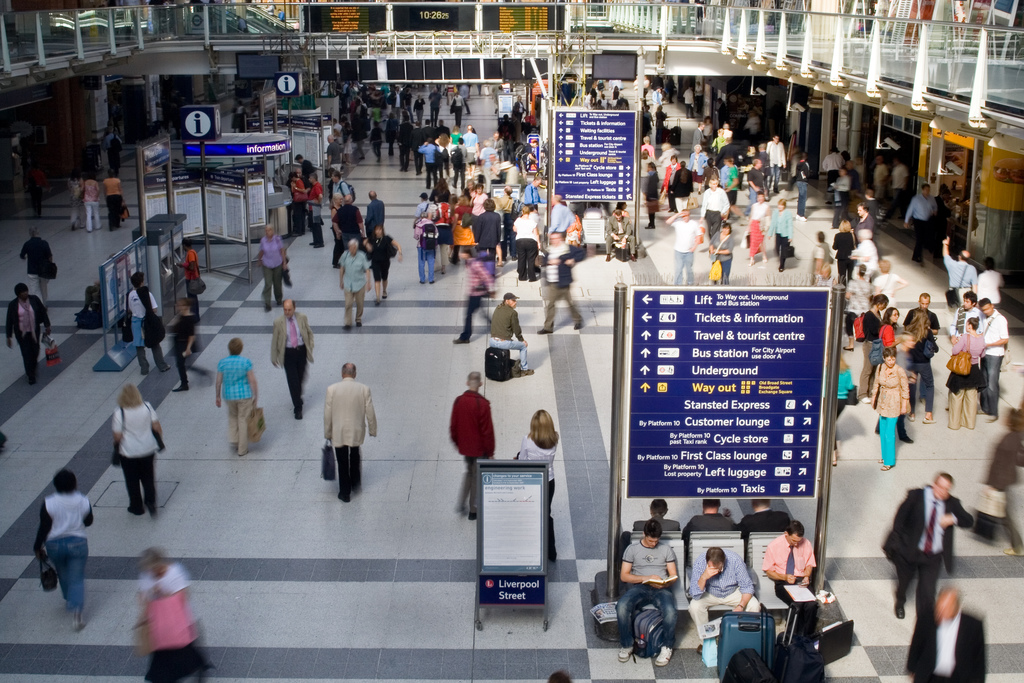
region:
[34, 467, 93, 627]
A woman in a white shirt and blue jeans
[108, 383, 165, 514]
A blond woman wearing a white blouse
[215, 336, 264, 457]
A lady wearing a blue shirt and khaki pants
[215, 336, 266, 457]
A woman carrying a bag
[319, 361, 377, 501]
A bald man in a long coat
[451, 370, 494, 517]
A man wearing a red jacket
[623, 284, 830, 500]
Blue information sign in a bus station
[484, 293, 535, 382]
A man wearing a hat and sitting on a suitcase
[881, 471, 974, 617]
A businessman walking quickly and checking his watch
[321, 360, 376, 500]
a man is walking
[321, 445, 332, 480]
the briefcase is brown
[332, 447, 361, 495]
the pants are black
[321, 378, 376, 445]
the jacket is tan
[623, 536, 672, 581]
the shirt is gray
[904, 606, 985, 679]
the jacket is black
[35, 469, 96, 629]
a woman is walking away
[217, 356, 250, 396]
the shirt is blue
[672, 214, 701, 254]
the shirt is white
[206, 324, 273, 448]
woman wearing blue shirt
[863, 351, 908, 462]
woman wearing blue pants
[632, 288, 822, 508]
blue sign on silver poles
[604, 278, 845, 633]
silver poles the sign is attached to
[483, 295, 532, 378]
man sitting on black luggage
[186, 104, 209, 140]
black i on white background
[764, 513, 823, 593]
man wearing pink shirt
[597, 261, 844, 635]
large sign above chairs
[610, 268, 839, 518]
large sign is blue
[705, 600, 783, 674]
luggage on floor is green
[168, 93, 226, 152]
square sign on pole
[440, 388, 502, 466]
man wearing red jacket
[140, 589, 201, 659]
woman holding pink bag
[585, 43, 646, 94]
television attached to balcony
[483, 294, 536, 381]
man is sitting on a suitcase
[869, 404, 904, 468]
woman has on aqua pants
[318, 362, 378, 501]
man is carrying a bag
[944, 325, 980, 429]
woman is carrying a purse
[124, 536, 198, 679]
a person is standing up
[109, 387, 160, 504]
a person is standing up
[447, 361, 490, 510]
a person is standing up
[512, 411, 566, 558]
a person is standing up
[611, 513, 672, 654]
a person is sitting down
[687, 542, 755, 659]
a person is sitting down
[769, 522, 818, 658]
a person is sitting down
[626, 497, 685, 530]
a person is sitting down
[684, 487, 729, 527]
a person is sitting down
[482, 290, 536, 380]
a man is sitting on his suitcase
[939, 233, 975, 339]
balding man in a blue shirt is pointing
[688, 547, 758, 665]
man in blue shirt leaning on his hand while sitting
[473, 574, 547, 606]
blue sign reads Liverpool Street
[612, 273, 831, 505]
blue and white sign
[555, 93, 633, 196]
blue and white sign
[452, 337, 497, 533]
man in a red jacket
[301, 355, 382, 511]
man in a grey suit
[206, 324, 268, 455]
woman in a blue shirt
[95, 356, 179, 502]
woman in a white shirt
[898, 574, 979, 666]
man in a black suit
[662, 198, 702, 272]
man in a white shirt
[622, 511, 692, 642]
man sitting down reading a book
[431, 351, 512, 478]
A person wearing a red coat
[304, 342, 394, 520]
A man is holding a bag